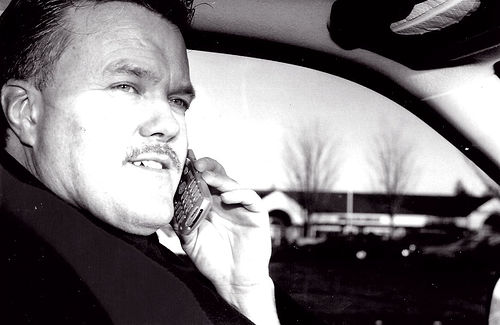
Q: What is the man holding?
A: A cell phone.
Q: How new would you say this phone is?
A: Not new.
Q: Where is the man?
A: In a car.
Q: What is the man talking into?
A: A cell phone.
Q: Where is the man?
A: In the car.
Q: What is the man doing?
A: Speaking on the phone.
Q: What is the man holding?
A: A cell phone.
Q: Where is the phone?
A: In the man's hand.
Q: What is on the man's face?
A: Mustache.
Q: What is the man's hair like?
A: Short, black.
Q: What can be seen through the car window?
A: Two trees.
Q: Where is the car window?
A: Behind the man.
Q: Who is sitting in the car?
A: A man.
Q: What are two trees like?
A: Barren.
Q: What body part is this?
A: Mouth.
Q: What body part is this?
A: Hand.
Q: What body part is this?
A: Mouth.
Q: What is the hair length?
A: Short.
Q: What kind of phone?
A: Cell phone.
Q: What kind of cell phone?
A: Flip phone.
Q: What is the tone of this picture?
A: Black and white.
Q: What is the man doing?
A: Talking.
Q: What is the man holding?
A: Phone.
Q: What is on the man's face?
A: Mustache.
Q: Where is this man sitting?
A: Inside car.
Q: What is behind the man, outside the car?
A: Building.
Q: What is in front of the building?
A: Trees.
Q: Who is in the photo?
A: A man.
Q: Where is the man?
A: In a car.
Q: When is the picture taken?
A: During the day.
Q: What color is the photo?
A: Black and white.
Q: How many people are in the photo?
A: One.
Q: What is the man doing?
A: Holding the phone.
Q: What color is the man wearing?
A: Black.